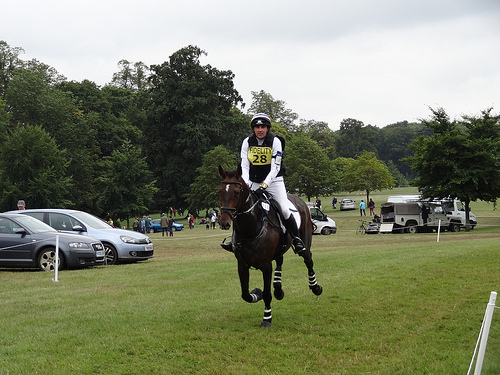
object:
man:
[240, 112, 304, 251]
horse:
[218, 163, 322, 328]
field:
[1, 185, 499, 375]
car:
[1, 213, 106, 271]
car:
[2, 207, 156, 264]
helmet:
[249, 111, 272, 129]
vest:
[247, 133, 287, 183]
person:
[357, 198, 368, 219]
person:
[365, 199, 378, 216]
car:
[143, 217, 183, 234]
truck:
[377, 196, 463, 238]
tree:
[412, 109, 500, 232]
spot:
[225, 180, 230, 192]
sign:
[249, 146, 275, 167]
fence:
[1, 236, 61, 251]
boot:
[283, 211, 306, 255]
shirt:
[358, 202, 365, 211]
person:
[187, 213, 196, 229]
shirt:
[190, 214, 195, 222]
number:
[249, 155, 266, 164]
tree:
[341, 150, 398, 209]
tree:
[283, 134, 344, 202]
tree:
[95, 138, 159, 231]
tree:
[1, 123, 77, 209]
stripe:
[263, 307, 274, 314]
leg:
[258, 260, 274, 328]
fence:
[467, 291, 495, 375]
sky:
[1, 1, 500, 129]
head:
[249, 112, 270, 139]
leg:
[301, 248, 322, 298]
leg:
[238, 256, 265, 305]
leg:
[269, 254, 286, 302]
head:
[214, 163, 243, 229]